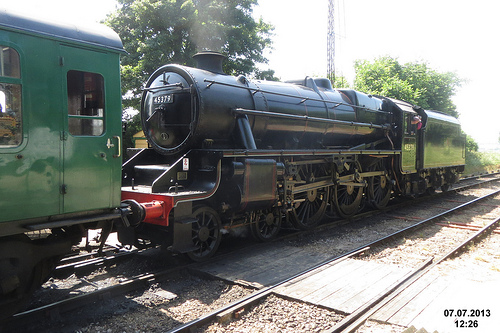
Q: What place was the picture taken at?
A: It was taken at the walkway.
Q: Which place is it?
A: It is a walkway.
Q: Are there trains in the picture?
A: Yes, there is a train.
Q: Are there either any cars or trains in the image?
A: Yes, there is a train.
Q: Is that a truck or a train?
A: That is a train.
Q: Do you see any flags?
A: No, there are no flags.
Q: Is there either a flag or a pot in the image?
A: No, there are no flags or pots.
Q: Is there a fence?
A: No, there are no fences.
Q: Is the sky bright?
A: Yes, the sky is bright.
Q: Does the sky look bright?
A: Yes, the sky is bright.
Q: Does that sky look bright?
A: Yes, the sky is bright.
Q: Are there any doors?
A: Yes, there is a door.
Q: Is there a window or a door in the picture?
A: Yes, there is a door.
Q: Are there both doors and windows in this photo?
A: Yes, there are both a door and a window.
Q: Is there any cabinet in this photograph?
A: No, there are no cabinets.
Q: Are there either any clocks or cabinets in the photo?
A: No, there are no cabinets or clocks.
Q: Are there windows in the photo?
A: Yes, there is a window.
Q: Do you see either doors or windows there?
A: Yes, there is a window.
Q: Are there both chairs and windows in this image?
A: No, there is a window but no chairs.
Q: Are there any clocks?
A: No, there are no clocks.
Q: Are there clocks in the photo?
A: No, there are no clocks.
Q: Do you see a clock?
A: No, there are no clocks.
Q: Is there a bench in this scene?
A: No, there are no benches.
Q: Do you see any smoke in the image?
A: Yes, there is smoke.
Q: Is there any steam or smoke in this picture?
A: Yes, there is smoke.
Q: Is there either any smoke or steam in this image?
A: Yes, there is smoke.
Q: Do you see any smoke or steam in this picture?
A: Yes, there is smoke.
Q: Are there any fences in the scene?
A: No, there are no fences.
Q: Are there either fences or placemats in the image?
A: No, there are no fences or placemats.